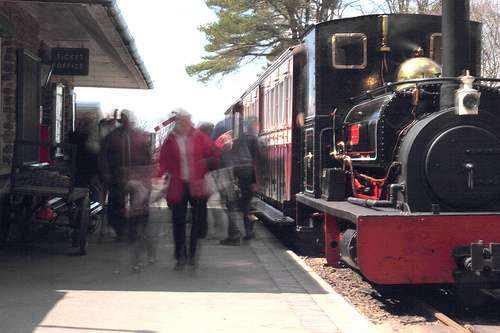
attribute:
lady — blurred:
[160, 111, 234, 275]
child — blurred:
[122, 173, 158, 272]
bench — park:
[6, 168, 107, 253]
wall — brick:
[1, 6, 73, 236]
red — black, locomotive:
[221, 0, 499, 290]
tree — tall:
[189, 0, 342, 82]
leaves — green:
[187, 1, 266, 81]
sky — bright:
[73, 0, 291, 133]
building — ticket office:
[1, 2, 154, 254]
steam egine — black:
[344, 1, 499, 203]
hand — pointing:
[220, 132, 233, 149]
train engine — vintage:
[296, 0, 498, 285]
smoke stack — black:
[437, 0, 475, 108]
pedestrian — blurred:
[101, 112, 149, 260]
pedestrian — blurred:
[214, 112, 259, 245]